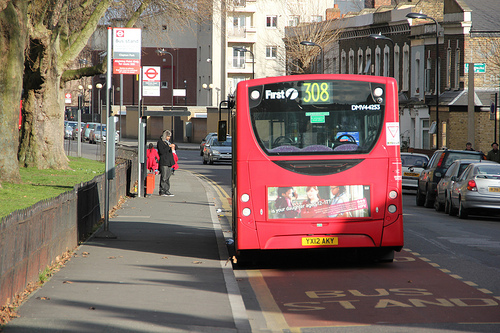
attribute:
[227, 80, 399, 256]
bus — red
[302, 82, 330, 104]
numbers — yellow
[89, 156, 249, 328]
sidewalk — gray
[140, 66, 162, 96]
sign — red, white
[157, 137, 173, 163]
coat — black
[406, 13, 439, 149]
street lamp — black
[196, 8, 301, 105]
building — gray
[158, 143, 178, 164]
jacket — black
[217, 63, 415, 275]
bus — large